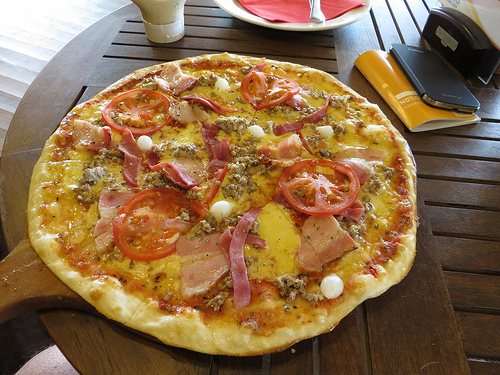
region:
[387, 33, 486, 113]
cell phone is black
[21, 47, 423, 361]
pizza is round in shape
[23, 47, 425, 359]
pizza has tomato on top of it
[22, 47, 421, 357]
ham on top of pizza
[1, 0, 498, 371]
table top is brown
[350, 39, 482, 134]
yellow book is under cell phone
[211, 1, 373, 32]
plate has red napkin in it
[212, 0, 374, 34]
plate is white in color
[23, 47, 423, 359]
there are some white balls in the pizza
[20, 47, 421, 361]
pizza has cheese on it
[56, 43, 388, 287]
a pizza on a table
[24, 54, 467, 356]
a pizza with lots of cheese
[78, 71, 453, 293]
a pizza with tomato sauce on it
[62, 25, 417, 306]
sliced tomatoes on a pizza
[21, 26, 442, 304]
a pizza sitting on a wood table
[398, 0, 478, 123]
a cell phone on a table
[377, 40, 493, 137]
a cell phone sitting on a small yellow book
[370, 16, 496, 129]
a black cell phone near a pizza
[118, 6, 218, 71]
a cup sitting on a table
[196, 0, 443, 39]
a plate sitting on a table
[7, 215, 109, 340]
pizza on a pizza board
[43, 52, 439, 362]
whole pizza on the board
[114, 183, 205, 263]
tomato on the pizza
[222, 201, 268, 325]
meat on the pizza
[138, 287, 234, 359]
crust of the pizza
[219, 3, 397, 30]
plate on the table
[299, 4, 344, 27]
silverware on the plate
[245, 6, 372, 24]
red napkin on the plate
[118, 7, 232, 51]
condiment on the table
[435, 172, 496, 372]
table is dark wood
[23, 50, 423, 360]
round breakfast-type pizza on serving dish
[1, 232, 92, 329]
wooden handle attached to serving dish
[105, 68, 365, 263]
tomato slices on top of pizza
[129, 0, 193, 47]
squeeze bottle of condiment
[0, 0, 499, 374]
wooden table for dining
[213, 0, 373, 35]
round white dinner plate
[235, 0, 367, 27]
red paper napkins on dinner plate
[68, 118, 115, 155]
piece of bacon on pizza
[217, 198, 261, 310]
strips of ham on pizza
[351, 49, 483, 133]
yellowish-gold activity planner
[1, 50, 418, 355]
Pizza on a wood board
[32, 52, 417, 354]
Pizza with cheese and toppings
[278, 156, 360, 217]
Slice of tomato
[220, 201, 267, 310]
Two strips of ham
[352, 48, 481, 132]
Yellow paper book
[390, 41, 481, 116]
Electronic in a case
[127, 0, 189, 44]
Upside down condiment bottle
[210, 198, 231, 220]
White ball of cheese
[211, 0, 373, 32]
White dinner plate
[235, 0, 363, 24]
Silverware on red paper napkin